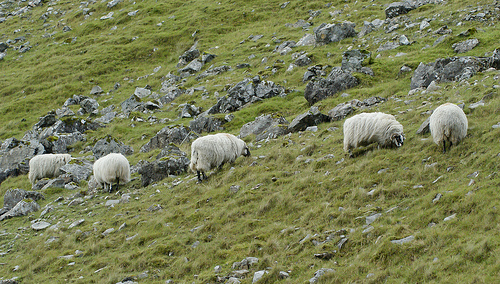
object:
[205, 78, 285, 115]
rocks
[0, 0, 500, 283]
grass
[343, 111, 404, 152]
sheep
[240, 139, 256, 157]
heads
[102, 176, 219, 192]
feet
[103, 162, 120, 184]
tail